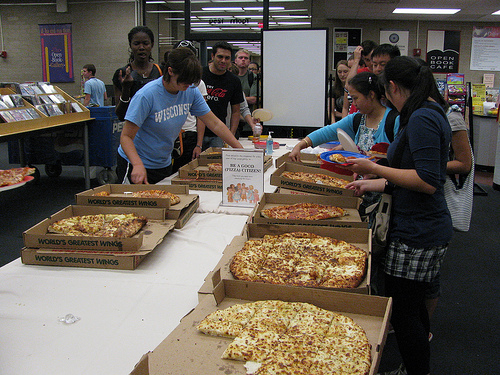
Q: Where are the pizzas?
A: In the boxes.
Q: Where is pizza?
A: In boxes.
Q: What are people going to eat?
A: Pizza.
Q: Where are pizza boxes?
A: On a table.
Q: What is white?
A: Table.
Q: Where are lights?
A: On the ceiling.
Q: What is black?
A: The floor.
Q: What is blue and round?
A: Plate.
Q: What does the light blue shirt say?
A: "WISCONSIN".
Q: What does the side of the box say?
A: "WORLD'S GREATEST WINGS".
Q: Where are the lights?
A: In the ceiling.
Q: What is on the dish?
A: Pizza.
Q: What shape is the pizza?
A: Round.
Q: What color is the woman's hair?
A: Brown.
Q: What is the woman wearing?
A: Leggings.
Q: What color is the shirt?
A: Blue.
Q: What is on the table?
A: Pizza boxes.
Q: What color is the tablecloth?
A: White.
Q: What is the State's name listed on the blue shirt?
A: Wisconsin.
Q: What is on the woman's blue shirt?
A: Wisconsin.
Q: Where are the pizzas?
A: On the table.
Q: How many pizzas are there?
A: Nine.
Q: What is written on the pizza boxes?
A: World's greatest wings.